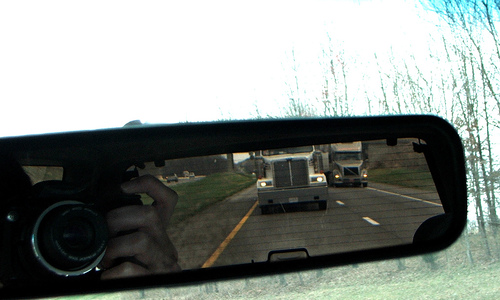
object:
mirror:
[0, 130, 447, 270]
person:
[0, 174, 178, 285]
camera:
[0, 172, 152, 283]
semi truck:
[238, 146, 334, 216]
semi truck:
[325, 146, 370, 190]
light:
[361, 173, 371, 179]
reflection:
[92, 134, 457, 279]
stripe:
[203, 203, 252, 267]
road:
[259, 224, 353, 243]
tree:
[229, 153, 233, 170]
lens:
[56, 218, 93, 253]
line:
[334, 199, 342, 206]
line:
[357, 211, 391, 229]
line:
[365, 184, 445, 209]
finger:
[124, 176, 166, 197]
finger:
[105, 205, 179, 259]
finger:
[109, 234, 162, 260]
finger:
[104, 264, 147, 278]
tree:
[177, 163, 197, 170]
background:
[216, 160, 222, 163]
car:
[165, 176, 182, 182]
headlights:
[259, 182, 267, 186]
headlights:
[334, 174, 341, 178]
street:
[163, 162, 326, 222]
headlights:
[316, 177, 323, 183]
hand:
[98, 171, 183, 280]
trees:
[480, 1, 498, 268]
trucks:
[313, 141, 375, 189]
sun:
[280, 3, 367, 57]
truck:
[251, 144, 338, 215]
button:
[117, 190, 133, 196]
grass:
[169, 172, 254, 219]